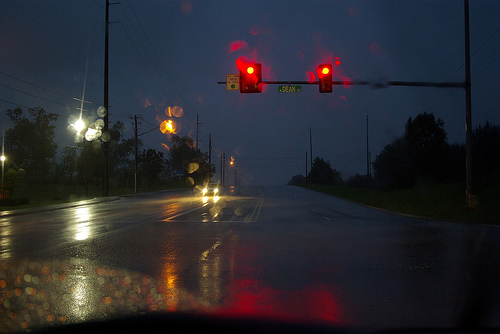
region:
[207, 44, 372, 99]
Lights on the road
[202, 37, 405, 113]
Street lighting in the photo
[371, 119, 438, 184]
Trees in the photo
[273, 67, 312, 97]
Signage in the photo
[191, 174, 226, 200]
Car on the road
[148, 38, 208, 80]
Dark skies in the photo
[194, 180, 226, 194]
Headlights of a car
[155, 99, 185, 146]
A street light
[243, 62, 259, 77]
a red light on pole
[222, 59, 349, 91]
2 red lights on a pole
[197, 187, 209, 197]
the head light of a car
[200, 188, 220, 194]
2 head lights of a car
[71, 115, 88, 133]
a lit street light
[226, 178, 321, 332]
a clear road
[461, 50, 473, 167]
a pole beside the road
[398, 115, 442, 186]
a tree beside the road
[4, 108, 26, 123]
leaves of a tree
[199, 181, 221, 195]
a car on the road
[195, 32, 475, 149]
red traffic light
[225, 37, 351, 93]
light is blurry because of water droplets on windshield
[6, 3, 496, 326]
view from inside car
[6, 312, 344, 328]
top of dashboard in car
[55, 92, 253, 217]
lens flare around the lights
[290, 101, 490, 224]
trees lining the streets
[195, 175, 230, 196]
car with lights on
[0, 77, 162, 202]
grass field with lots of trees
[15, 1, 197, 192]
telephone pole and telephone lines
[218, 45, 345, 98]
a pair of traffic lights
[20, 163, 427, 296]
the ground is wer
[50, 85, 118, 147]
glare on the lights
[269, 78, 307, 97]
a green and white sign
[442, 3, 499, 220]
pole on the side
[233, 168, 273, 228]
lines on the road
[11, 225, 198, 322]
water on the windshield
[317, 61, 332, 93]
traffic light with the red light on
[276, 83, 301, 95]
green road sign between the traffic lights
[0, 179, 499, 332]
shiny wet asphalt road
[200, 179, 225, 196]
car with the headlights on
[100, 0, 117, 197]
powerline pole on the left side of the road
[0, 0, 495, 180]
dark sky above the road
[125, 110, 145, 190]
powerline pole on the left side of the road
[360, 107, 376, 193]
powerline pole on the right side of the road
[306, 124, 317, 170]
powerline pole on the left side of the road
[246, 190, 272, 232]
two yellow lines painted on a street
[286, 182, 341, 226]
white lines painted on a street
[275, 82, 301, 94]
a green and white street sign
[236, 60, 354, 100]
two traffic lights on a pole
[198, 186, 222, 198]
a vehicle with its headlights on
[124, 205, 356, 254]
a paved street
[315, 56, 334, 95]
a traffic light on a pole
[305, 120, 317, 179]
a wood electrical pole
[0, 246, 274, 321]
a windshield with rain on it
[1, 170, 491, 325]
wet stretch of roadway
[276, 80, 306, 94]
green and white street sign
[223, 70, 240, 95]
white sign on the pole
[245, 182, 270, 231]
double yellow line on the road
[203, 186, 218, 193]
headlights of a car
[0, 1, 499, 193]
dark blue colored sky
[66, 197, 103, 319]
reflection of a white light on the road